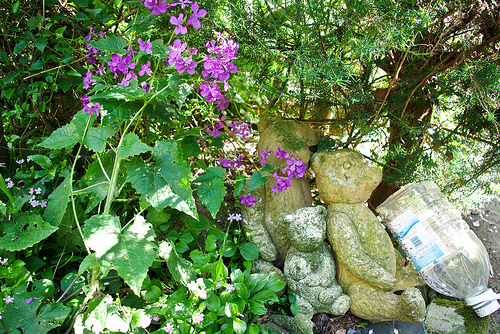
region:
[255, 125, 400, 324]
There are 3 bear statutes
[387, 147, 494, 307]
There is an empty plastic bottle laying next to one of the bears.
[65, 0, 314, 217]
The flowers on the foliage is purple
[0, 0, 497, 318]
This picture is taken during the day.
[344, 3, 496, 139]
There is a small tree in the picture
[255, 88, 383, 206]
These two bears are brownish in color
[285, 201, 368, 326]
The small bear looks greyish in colour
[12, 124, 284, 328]
There are several different types of plants in this picture.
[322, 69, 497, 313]
The empty water bottle is facing down and leaning on one of the bears.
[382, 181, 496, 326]
The water bottle has lid on it.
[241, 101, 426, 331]
Three stone bears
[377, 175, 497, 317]
plastic bottle in a garden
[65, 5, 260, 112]
purple flowers in a garden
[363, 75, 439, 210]
tree trunk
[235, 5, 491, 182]
garden tree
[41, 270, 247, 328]
white flowers in the garden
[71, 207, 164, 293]
green leaf in a garden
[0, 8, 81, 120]
vines in a garden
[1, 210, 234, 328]
ground cover in a garden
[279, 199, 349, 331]
stone baby bear in a garden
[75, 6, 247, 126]
Small purple flowers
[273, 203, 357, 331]
Small bear figure that is worn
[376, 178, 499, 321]
half a plastic bottle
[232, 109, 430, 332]
bears of various sizes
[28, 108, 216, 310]
Heart shaped green leaves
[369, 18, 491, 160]
Tree with small branches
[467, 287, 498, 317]
white cap of bottle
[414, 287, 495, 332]
Mossy small rock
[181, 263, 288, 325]
small green leaves close to ground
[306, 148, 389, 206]
head of weather worn bear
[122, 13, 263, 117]
A bunch of purple flowers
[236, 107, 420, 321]
Three bear statues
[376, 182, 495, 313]
Clear water bottle with blue and white label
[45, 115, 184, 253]
Green leaves and stems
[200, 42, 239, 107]
Beautiful purple flower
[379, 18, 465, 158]
Small brown tree with green leaves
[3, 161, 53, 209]
small light purple flower with large green leaves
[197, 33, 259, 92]
Deep purple flower in front of greenery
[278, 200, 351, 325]
Small bear statue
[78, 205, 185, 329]
Green leaves with sun shining on them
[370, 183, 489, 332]
empty clear water bottle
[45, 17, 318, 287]
plant with purple flowers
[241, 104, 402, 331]
three bears made of stone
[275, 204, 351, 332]
small grey bear made of stone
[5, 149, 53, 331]
plant with small light purple flowers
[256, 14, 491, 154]
plant with green needles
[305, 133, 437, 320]
tan bear made of stone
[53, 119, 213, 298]
plant with large green leaves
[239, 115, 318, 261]
tan bear made of stone in background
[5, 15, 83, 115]
plant with medium green leaves